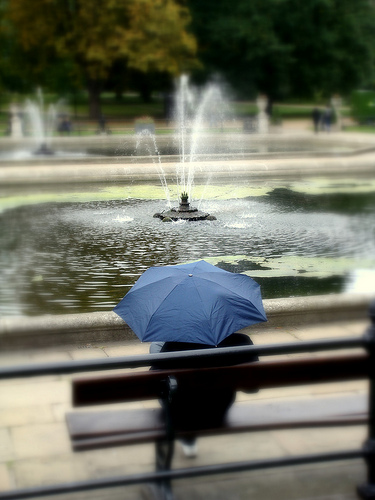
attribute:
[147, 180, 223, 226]
fountain — black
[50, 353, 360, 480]
bench — metal, wood, brown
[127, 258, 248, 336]
umbrella — blue, opened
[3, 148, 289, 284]
fountain — water, center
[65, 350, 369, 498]
bench — dark, metal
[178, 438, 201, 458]
shoe — white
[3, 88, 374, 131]
grass — green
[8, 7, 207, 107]
tree — light colored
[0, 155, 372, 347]
water fountain — concrete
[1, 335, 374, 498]
railing — black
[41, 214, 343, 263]
water — green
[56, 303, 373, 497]
bench — brown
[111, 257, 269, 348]
umberella — blue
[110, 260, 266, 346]
umbrella — open, blue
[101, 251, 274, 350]
umbrella — dark, blue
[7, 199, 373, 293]
pond — brown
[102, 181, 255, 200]
scum — green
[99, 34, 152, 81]
leaves — green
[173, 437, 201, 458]
shoes — white 